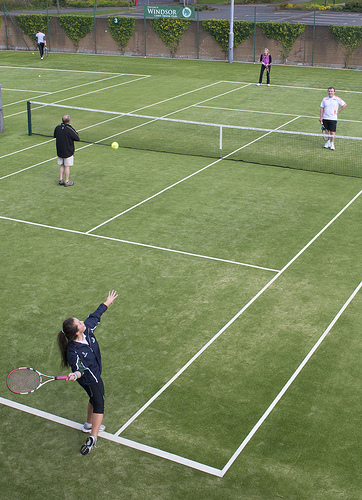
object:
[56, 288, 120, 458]
person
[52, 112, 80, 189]
person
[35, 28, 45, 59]
person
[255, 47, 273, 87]
person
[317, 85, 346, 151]
person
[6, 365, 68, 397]
racket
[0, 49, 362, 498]
court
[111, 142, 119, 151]
ball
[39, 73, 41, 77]
ball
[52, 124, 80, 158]
jacket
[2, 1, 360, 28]
parking lot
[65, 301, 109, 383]
jacket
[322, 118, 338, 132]
shorts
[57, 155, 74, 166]
shorts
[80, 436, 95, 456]
sneaker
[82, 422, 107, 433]
sneaker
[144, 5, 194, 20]
sign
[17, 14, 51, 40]
ivy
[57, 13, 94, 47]
ivy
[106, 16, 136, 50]
ivy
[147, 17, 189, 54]
ivy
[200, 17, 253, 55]
ivy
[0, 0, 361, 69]
fence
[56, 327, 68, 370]
ponytail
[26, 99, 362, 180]
net